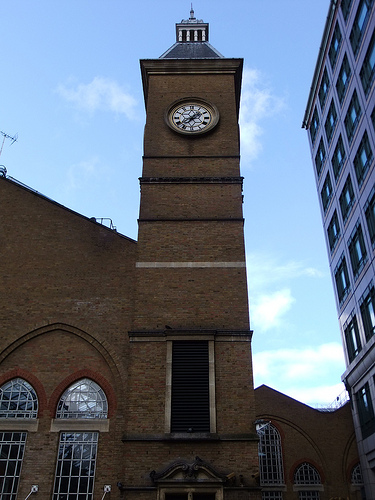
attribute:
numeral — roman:
[186, 102, 197, 113]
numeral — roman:
[174, 119, 182, 124]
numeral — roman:
[202, 114, 211, 123]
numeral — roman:
[181, 120, 187, 131]